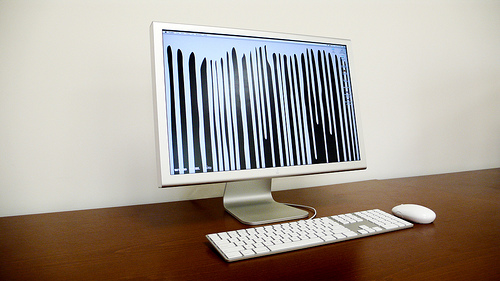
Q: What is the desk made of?
A: Wood.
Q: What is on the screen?
A: A black and white image.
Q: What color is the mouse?
A: White.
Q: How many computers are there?
A: One.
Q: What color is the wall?
A: White.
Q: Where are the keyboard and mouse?
A: On a desk.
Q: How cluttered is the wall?
A: Not cluttered at all.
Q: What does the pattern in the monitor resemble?
A: A barcode.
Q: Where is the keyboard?
A: In front of the monitor.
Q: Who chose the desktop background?
A: Computer user.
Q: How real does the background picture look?
A: Somewhat real.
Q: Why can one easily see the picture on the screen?
A: Monitor is large.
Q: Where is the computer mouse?
A: To the right of the keyboard.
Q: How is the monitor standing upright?
A: A steel foot.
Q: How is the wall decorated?
A: Plainly.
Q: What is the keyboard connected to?
A: The monitor.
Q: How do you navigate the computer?
A: With the mouse.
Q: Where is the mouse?
A: Next to the keyboard.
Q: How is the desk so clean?
A: No clutter.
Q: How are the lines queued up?
A: Randomly.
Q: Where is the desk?
A: Under the keyboard.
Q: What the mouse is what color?
A: White.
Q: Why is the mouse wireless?
A: Ease of operation.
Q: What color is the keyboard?
A: White.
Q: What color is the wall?
A: Off white.